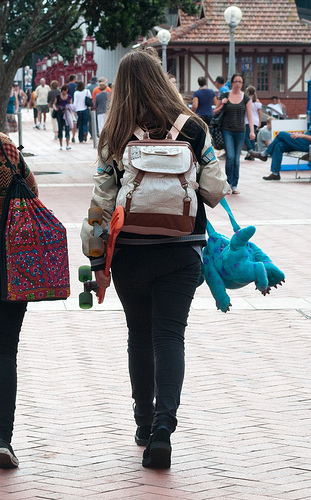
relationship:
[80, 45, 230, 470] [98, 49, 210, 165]
girl with hair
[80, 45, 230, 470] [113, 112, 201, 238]
girl wearing backpack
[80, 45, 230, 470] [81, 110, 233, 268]
girl wearing jacket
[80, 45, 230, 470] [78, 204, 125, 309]
girl carrying skateboard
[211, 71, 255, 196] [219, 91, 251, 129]
woman wearing tanktop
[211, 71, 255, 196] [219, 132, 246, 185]
woman wearing bluejeans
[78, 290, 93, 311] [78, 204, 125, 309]
wheel of skateboard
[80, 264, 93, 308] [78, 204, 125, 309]
wheels of skateboard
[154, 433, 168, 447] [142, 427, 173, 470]
back of shoe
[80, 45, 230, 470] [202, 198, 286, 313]
girl carrying bag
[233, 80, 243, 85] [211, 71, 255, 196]
eyeglasses of woman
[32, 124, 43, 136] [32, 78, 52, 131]
shoe of man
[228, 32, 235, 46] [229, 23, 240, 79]
part of pole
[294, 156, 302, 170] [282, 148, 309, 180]
part of bench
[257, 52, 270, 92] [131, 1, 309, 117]
window of building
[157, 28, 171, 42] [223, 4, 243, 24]
sphere on light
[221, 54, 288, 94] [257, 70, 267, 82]
windows with panes